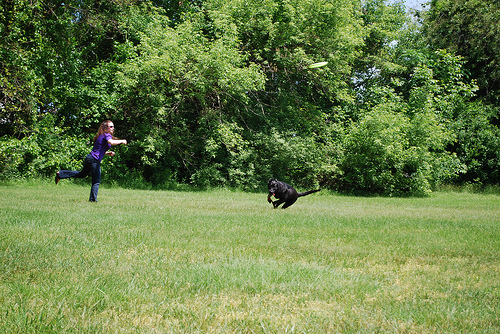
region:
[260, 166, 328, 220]
THE DOG IS BLACK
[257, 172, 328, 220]
THE DOG IS RUNNING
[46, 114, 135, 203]
THE GIRL IS STANDING ON ONE LEG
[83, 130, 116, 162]
THE GIRL IS WEARING A PURPLE SHIRT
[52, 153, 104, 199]
THE GIRL IS WEARING JEANS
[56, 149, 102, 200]
THE JEANS ARE DARK BLUE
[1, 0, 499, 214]
THE TREES ARE TALL AND GREEN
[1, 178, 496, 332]
THE GRASS IS LUSH AND GREEN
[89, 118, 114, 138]
THE WOMAN HAS LONG HAIR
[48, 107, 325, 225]
THE WOMAN IS PLAYING WITH THE DOG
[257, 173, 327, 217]
black dog jumping in air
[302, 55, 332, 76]
green frisbee flying through air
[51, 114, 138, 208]
red head woman with purple shirt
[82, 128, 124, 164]
ladies purple casual shirt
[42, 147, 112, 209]
dark blue denim pants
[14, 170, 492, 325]
large grassy field for play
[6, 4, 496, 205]
dense grove of background trees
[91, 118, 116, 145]
red hair on white female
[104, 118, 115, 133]
dark sunglasses on white lady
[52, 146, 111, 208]
right leg pushed up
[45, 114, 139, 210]
This is a woman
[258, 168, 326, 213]
This a black dog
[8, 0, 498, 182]
This is a forest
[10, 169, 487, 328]
This is a field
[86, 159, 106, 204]
Leg of a woman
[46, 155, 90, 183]
Leg of a woman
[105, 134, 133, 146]
Hand of a woman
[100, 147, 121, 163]
Hand of a woman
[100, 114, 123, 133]
Head of a woman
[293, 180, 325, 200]
Tail of a dog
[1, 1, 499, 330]
woman playing with dog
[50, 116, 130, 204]
woman running on grass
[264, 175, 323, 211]
dog running on grass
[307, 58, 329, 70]
Frisbee in the air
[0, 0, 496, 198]
trees at edge of grass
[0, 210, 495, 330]
a patch of grass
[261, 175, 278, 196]
dog's head with tongue hanging out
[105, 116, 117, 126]
woman's sunglasses with dark tint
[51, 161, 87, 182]
the woman's bent leg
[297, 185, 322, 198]
the dog's tail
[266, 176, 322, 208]
black dog is running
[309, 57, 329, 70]
green Frisbee above green grass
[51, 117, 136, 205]
person is throwing a Frisbee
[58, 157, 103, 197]
person wearing blue jeans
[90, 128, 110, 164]
person wearing a blue t shirt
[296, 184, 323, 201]
black tail is extended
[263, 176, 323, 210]
dog is chasing Frisbee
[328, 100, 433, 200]
green bush behind dog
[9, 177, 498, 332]
grass beneath dog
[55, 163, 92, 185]
person's leg above grass